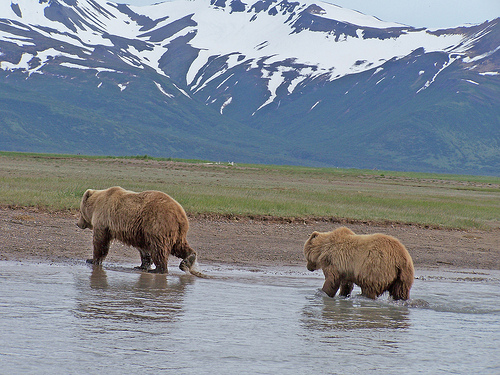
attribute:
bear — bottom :
[299, 220, 416, 305]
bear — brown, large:
[318, 220, 410, 291]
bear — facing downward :
[303, 224, 414, 301]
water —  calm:
[68, 285, 348, 368]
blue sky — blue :
[325, 0, 499, 28]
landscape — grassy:
[29, 111, 482, 195]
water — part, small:
[2, 257, 496, 374]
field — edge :
[1, 146, 498, 225]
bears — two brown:
[75, 183, 418, 301]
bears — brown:
[73, 175, 419, 312]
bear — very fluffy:
[298, 207, 415, 287]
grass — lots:
[7, 108, 491, 160]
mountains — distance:
[1, 3, 498, 174]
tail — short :
[173, 218, 200, 279]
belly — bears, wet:
[344, 276, 367, 286]